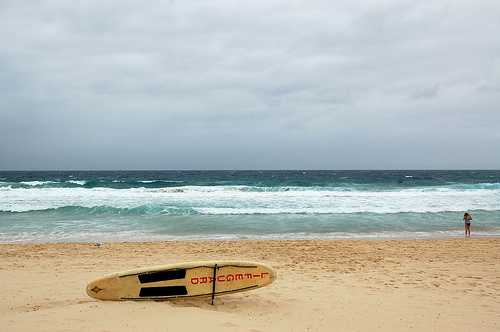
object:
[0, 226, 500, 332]
beach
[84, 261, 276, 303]
device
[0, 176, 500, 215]
wave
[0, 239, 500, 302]
tracks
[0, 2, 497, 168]
cloud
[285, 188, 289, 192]
person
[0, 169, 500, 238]
ocean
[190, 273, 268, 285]
red letters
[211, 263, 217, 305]
black handles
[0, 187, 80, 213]
rough surf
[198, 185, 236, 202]
white waves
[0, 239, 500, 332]
brown sand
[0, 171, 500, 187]
blue water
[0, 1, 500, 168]
cloudy sky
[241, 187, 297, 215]
water crashing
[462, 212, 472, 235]
girl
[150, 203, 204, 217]
small waves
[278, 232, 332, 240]
water mixed